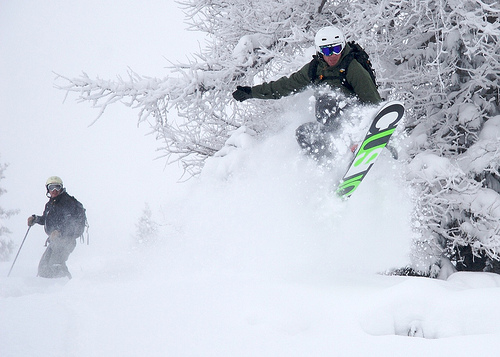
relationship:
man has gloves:
[275, 31, 398, 187] [237, 74, 260, 114]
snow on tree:
[42, 20, 226, 178] [58, 15, 498, 180]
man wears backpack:
[275, 31, 398, 187] [334, 32, 377, 76]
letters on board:
[344, 115, 391, 201] [317, 104, 401, 216]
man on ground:
[7, 167, 113, 287] [82, 274, 487, 352]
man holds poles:
[7, 167, 113, 287] [0, 220, 63, 289]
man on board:
[275, 31, 398, 187] [317, 104, 401, 216]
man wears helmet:
[275, 31, 398, 187] [317, 30, 342, 47]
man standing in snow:
[7, 167, 113, 287] [10, 288, 172, 349]